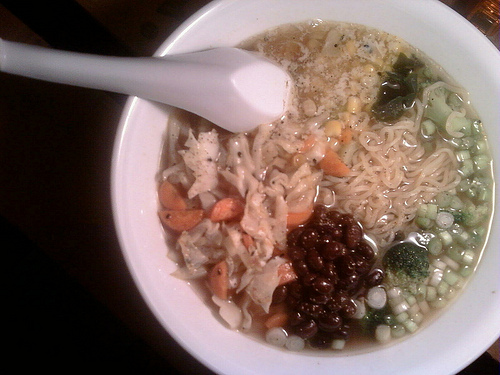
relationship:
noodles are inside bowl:
[317, 79, 441, 234] [110, 1, 498, 372]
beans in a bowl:
[286, 209, 371, 336] [110, 1, 498, 372]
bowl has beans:
[110, 1, 498, 372] [286, 209, 371, 336]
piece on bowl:
[156, 209, 203, 228] [110, 1, 498, 372]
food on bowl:
[144, 32, 496, 349] [110, 1, 498, 372]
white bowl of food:
[99, 2, 499, 373] [144, 32, 496, 349]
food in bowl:
[203, 192, 251, 224] [110, 1, 498, 372]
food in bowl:
[144, 32, 496, 349] [110, 1, 498, 372]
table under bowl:
[0, 1, 498, 373] [110, 1, 498, 372]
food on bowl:
[282, 189, 387, 367] [110, 1, 498, 372]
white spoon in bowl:
[22, 41, 297, 117] [122, 44, 499, 350]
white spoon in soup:
[22, 41, 297, 117] [194, 84, 420, 321]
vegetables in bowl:
[172, 123, 372, 308] [110, 1, 498, 372]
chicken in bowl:
[190, 206, 288, 319] [110, 1, 498, 372]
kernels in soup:
[312, 93, 372, 158] [121, 7, 499, 368]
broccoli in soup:
[387, 222, 447, 295] [157, 18, 497, 356]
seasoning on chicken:
[185, 127, 230, 191] [164, 128, 305, 322]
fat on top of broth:
[327, 71, 362, 88] [303, 26, 346, 51]